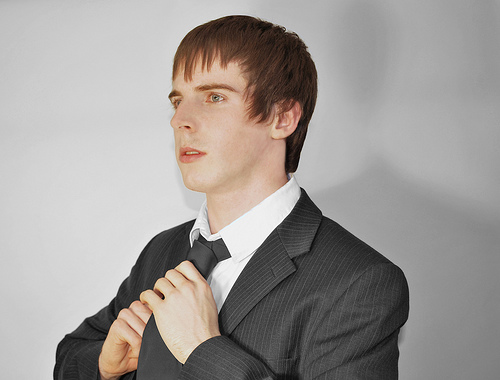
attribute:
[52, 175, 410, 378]
clothing — professional 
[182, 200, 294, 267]
collar — down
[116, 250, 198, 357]
fingers — clasped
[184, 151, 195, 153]
teeth — white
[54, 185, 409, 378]
suit coat — grey , pin striped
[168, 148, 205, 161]
mouth — slightly open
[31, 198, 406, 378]
jacket — is striped, black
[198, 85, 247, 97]
eyebrow — is long, is thin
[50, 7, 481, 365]
man — young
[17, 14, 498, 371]
wall — white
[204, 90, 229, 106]
eye — is green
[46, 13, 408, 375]
young man — young 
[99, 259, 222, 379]
hands — pale 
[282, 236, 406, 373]
pin stripes — thin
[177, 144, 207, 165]
lips — pink, parted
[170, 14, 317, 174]
hair — feathered, short, red